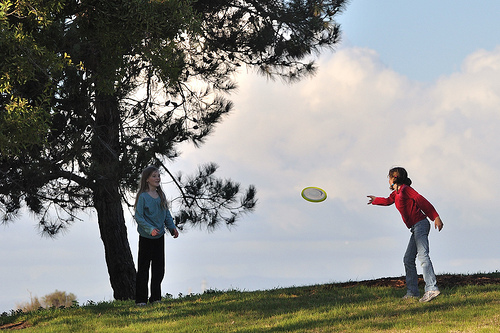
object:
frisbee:
[300, 187, 327, 203]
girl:
[366, 166, 446, 304]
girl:
[134, 166, 180, 304]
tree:
[1, 0, 350, 300]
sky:
[1, 0, 499, 313]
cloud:
[168, 0, 500, 222]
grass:
[1, 269, 500, 332]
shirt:
[134, 190, 176, 237]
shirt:
[372, 184, 440, 228]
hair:
[390, 166, 412, 187]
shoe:
[419, 290, 441, 301]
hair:
[134, 166, 169, 210]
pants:
[134, 234, 165, 302]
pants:
[403, 216, 439, 295]